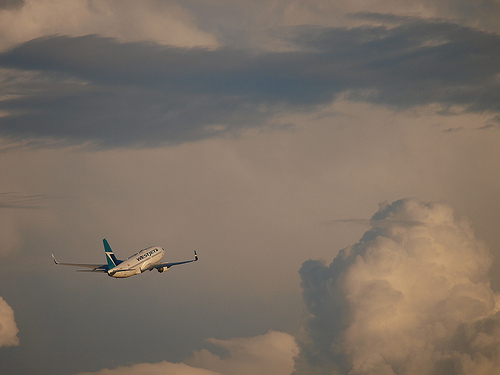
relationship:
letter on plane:
[144, 242, 162, 260] [36, 226, 255, 314]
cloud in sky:
[352, 214, 428, 283] [155, 100, 280, 157]